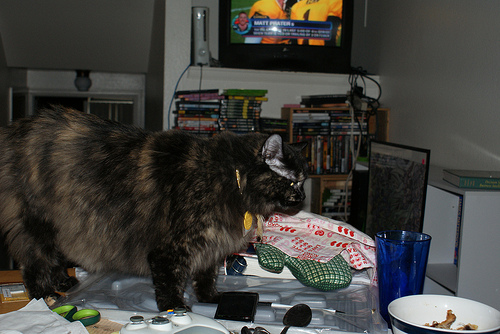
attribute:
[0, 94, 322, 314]
cat — black, blown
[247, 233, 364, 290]
mitt — green, white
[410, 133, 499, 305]
shelf — white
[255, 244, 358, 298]
mitt — green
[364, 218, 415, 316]
glass — blue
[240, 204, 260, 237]
tag — yellow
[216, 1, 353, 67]
tv — on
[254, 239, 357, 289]
mitts — green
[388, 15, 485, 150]
wall — cream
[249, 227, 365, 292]
oven mitt — green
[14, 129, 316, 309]
cat — adult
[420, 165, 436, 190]
frame — thin, black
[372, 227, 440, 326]
glass — dark blue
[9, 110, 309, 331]
cat — dark gray, fluffy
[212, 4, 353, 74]
television — black framed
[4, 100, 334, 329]
cat — fat, very fluffy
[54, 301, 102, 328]
scissor handles — green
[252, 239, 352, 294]
oven mit — green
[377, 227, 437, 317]
cup — blue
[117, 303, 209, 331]
controller — white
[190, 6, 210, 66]
console — white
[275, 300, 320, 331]
spoon — silver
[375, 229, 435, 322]
cup — cobalt blue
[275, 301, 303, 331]
spoon — large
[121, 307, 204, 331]
controller — white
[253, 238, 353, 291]
oven mitt — green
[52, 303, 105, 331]
handle — green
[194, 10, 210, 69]
console — white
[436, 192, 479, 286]
shelf — white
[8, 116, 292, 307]
cat — fat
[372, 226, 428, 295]
glass — water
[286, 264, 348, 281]
mitt — oven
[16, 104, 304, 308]
cat — big, furry